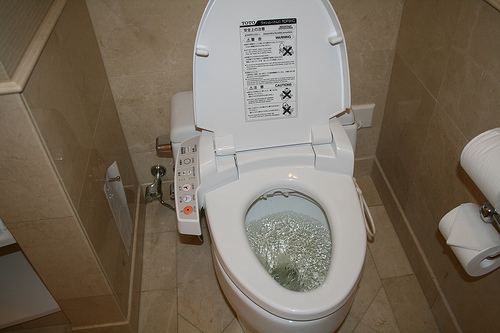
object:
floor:
[135, 174, 454, 333]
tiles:
[360, 204, 415, 280]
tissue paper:
[456, 127, 499, 216]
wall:
[367, 0, 499, 332]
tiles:
[377, 53, 439, 182]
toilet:
[167, 0, 368, 332]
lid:
[191, 0, 353, 157]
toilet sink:
[242, 186, 335, 293]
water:
[245, 210, 332, 292]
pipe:
[151, 169, 175, 211]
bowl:
[203, 165, 368, 320]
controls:
[183, 204, 193, 214]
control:
[153, 133, 173, 158]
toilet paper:
[436, 202, 499, 276]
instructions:
[236, 16, 298, 123]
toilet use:
[168, 1, 361, 332]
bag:
[101, 160, 135, 257]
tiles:
[0, 214, 112, 302]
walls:
[21, 0, 146, 332]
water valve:
[146, 163, 166, 181]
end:
[443, 202, 498, 252]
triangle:
[445, 203, 482, 253]